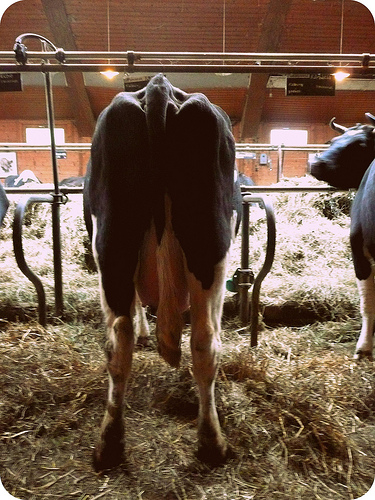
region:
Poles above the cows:
[10, 30, 374, 80]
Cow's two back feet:
[80, 376, 240, 470]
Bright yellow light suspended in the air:
[326, 63, 351, 87]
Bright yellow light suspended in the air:
[96, 65, 119, 85]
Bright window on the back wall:
[266, 128, 312, 148]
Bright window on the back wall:
[21, 121, 68, 152]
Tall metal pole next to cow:
[19, 38, 80, 319]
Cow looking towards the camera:
[306, 106, 374, 366]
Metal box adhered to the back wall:
[258, 146, 271, 170]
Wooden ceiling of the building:
[7, 8, 368, 53]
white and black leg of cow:
[347, 242, 372, 359]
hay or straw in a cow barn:
[253, 360, 370, 481]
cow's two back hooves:
[88, 425, 236, 475]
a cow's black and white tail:
[136, 72, 189, 374]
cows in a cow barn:
[2, 173, 373, 407]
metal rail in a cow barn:
[240, 182, 289, 352]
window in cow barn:
[21, 126, 68, 151]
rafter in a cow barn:
[237, 59, 271, 138]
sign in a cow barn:
[278, 66, 341, 99]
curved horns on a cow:
[324, 108, 373, 139]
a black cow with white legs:
[76, 73, 265, 489]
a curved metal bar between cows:
[244, 189, 278, 372]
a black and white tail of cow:
[137, 86, 186, 376]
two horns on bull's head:
[322, 107, 374, 147]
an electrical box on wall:
[255, 144, 268, 167]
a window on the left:
[20, 121, 89, 157]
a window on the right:
[268, 125, 311, 155]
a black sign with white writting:
[280, 68, 348, 110]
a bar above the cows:
[13, 29, 373, 98]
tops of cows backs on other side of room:
[7, 161, 87, 200]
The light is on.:
[99, 67, 120, 82]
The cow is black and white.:
[81, 70, 236, 467]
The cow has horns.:
[327, 112, 374, 132]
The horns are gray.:
[328, 111, 373, 129]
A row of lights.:
[99, 68, 352, 83]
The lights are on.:
[98, 67, 351, 80]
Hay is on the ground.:
[0, 311, 373, 499]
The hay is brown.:
[0, 187, 373, 498]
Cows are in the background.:
[0, 167, 259, 189]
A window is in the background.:
[268, 126, 309, 149]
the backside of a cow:
[78, 78, 248, 469]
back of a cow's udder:
[139, 239, 190, 314]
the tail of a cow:
[143, 74, 184, 369]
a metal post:
[39, 71, 64, 312]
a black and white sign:
[283, 77, 335, 96]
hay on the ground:
[227, 347, 373, 498]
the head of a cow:
[308, 116, 373, 184]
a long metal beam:
[0, 60, 374, 78]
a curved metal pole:
[240, 191, 278, 343]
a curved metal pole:
[10, 195, 67, 318]